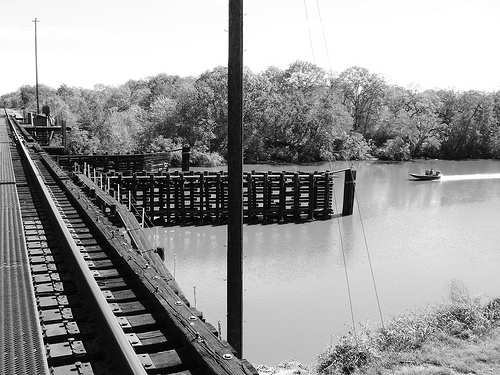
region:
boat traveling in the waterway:
[405, 157, 442, 187]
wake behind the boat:
[443, 166, 498, 181]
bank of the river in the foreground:
[329, 306, 486, 373]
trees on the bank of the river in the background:
[41, 69, 488, 159]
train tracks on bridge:
[3, 105, 190, 365]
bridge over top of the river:
[8, 101, 222, 373]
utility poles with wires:
[225, 5, 382, 357]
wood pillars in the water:
[178, 142, 358, 217]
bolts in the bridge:
[11, 106, 236, 365]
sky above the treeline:
[6, 16, 496, 87]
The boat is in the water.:
[403, 160, 453, 187]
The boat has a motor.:
[407, 162, 453, 187]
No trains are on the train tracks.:
[0, 99, 96, 338]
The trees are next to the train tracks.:
[2, 77, 94, 219]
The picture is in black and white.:
[0, 3, 499, 365]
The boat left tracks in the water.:
[407, 154, 498, 191]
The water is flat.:
[386, 203, 465, 249]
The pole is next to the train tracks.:
[17, 9, 52, 164]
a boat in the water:
[407, 162, 452, 190]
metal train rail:
[54, 214, 94, 280]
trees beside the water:
[272, 80, 459, 172]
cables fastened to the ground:
[324, 150, 402, 367]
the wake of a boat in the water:
[429, 161, 498, 183]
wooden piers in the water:
[258, 172, 342, 234]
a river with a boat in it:
[300, 120, 495, 338]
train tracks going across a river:
[5, 101, 268, 361]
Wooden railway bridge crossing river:
[2, 108, 256, 373]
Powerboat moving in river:
[408, 169, 441, 180]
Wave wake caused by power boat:
[439, 174, 496, 181]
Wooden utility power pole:
[225, 2, 244, 356]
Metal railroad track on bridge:
[4, 106, 146, 374]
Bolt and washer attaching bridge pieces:
[186, 313, 198, 323]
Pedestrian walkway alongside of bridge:
[69, 160, 221, 332]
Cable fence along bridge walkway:
[72, 159, 233, 346]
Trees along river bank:
[0, 64, 499, 162]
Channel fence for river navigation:
[98, 167, 360, 226]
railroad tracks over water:
[3, 109, 170, 374]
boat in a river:
[409, 168, 441, 183]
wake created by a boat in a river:
[438, 170, 498, 182]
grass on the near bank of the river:
[288, 276, 499, 369]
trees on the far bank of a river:
[21, 63, 495, 164]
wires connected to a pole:
[298, 0, 392, 354]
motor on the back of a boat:
[435, 169, 442, 176]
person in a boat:
[425, 167, 434, 177]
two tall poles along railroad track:
[28, 3, 248, 356]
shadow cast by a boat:
[406, 175, 427, 182]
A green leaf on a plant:
[176, 85, 183, 89]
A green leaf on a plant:
[188, 91, 190, 93]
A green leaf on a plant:
[145, 91, 148, 93]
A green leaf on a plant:
[272, 102, 274, 104]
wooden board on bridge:
[136, 346, 184, 368]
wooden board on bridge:
[125, 324, 165, 352]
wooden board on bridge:
[107, 301, 145, 313]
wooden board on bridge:
[96, 274, 125, 290]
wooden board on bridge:
[45, 338, 82, 361]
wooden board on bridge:
[41, 320, 78, 335]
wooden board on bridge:
[40, 308, 77, 321]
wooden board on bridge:
[34, 280, 57, 296]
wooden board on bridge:
[31, 261, 58, 272]